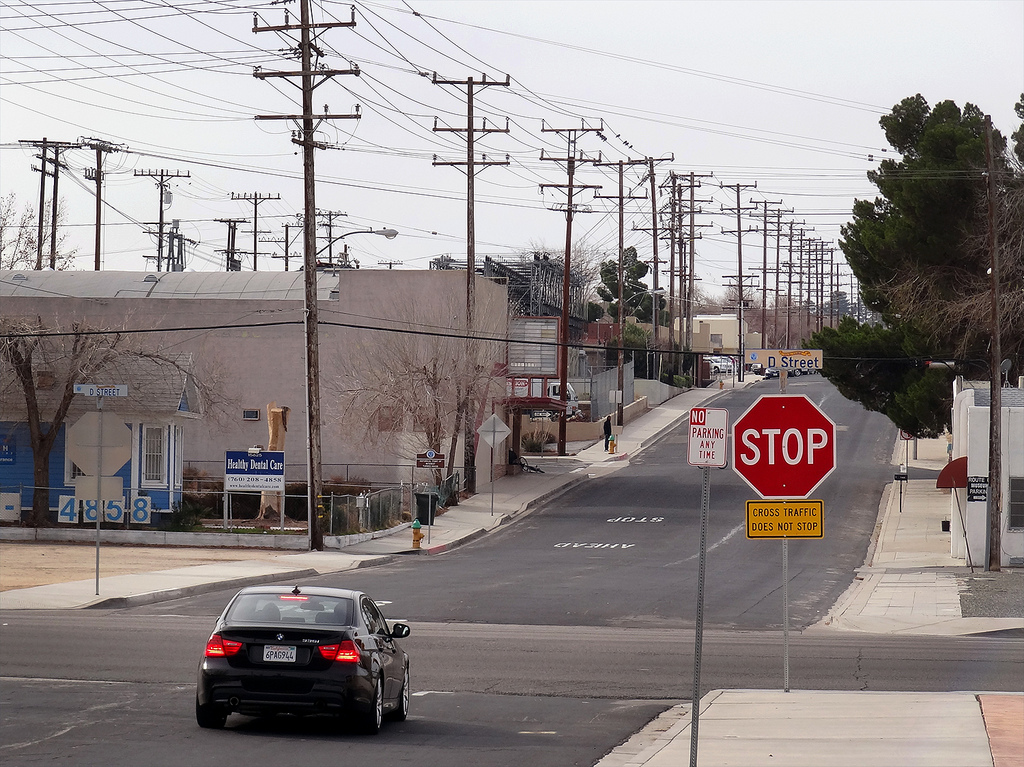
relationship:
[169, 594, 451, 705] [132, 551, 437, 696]
lights on car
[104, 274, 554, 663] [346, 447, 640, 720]
streets in city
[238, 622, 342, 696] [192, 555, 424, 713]
license plate on car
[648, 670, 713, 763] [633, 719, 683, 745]
side on sidewalk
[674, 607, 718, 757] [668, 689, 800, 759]
pole on sidewalk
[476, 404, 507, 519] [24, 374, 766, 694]
pole on sidewalk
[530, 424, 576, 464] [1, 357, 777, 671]
pole on sidewalk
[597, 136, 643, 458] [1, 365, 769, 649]
pole on sidewalk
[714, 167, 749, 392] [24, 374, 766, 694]
pole on sidewalk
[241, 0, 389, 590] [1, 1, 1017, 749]
pole in city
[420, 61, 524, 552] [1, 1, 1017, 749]
pole in city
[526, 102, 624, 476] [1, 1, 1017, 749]
pole in city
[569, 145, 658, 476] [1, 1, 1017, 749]
pole in city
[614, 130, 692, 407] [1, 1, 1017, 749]
pole in city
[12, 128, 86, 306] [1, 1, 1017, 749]
pole in city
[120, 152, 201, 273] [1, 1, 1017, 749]
pole in city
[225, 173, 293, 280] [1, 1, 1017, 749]
pole in city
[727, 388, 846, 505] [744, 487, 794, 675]
stop sign on pole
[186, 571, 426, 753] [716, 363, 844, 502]
car sitting at stop sign